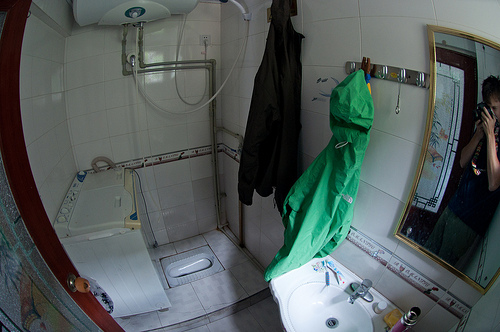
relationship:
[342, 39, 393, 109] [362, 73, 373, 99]
pliers with handle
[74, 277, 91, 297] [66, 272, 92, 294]
cover on door knob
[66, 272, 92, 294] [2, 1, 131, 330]
door knob on door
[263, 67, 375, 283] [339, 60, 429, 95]
jacket on stainless hook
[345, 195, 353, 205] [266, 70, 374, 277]
brand on jacket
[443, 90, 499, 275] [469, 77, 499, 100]
man has hair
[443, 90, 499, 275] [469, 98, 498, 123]
man has camera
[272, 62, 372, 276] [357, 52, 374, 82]
jacket on hook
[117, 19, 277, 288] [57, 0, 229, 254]
pipes on tile wall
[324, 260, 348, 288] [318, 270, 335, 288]
toothpaste tube by toothbrush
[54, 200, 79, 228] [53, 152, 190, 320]
buttons on appliances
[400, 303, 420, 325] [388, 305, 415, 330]
lid on bottle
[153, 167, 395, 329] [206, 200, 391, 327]
top view of sink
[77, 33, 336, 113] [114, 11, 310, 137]
cable plugged into wall